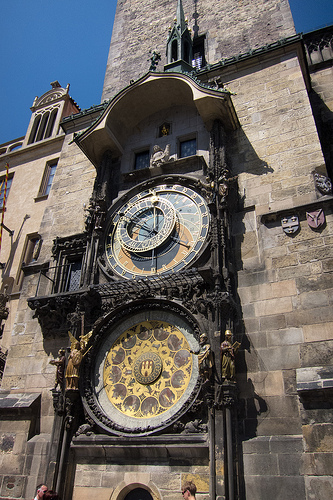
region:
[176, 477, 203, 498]
head of a person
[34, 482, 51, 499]
head of a person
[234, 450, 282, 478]
brick in a wall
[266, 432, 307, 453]
brick in a wall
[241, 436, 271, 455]
brick in a wall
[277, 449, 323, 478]
brick in a wall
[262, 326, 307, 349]
brick in a wall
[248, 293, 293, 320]
brick in a wall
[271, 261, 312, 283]
brick in a wall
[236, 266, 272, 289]
brick in a wall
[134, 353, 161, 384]
Yellow centerpiece inside of dish.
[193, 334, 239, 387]
Statues of men holding something.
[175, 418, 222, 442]
Statue of someone laying down.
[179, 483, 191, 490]
Man with glasses on his head.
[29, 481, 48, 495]
Top of walking man's head.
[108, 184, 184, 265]
Fancy clock above building.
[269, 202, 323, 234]
Small face statues on the wall.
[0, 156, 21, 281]
Red and white pole hanging from building.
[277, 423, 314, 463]
Piece of bricks on a building.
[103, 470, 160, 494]
Opening of the building.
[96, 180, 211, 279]
a clock on a wall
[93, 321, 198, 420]
symbols in a circle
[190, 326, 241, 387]
statues on the left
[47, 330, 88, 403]
statues on the right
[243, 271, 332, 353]
a stone block wall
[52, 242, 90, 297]
a window on the wall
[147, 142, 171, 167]
a statue on the top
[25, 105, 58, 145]
a row of windows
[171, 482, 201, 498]
top of a mans head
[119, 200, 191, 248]
hands on a clock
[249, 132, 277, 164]
shadow on the building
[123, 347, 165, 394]
round object on building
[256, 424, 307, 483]
brick wall in the photo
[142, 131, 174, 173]
object above the clock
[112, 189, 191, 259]
hands on the object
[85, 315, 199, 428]
yellow object on wall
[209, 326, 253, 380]
statue next to object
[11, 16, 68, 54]
blue sky above building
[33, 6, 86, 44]
sky with no clouds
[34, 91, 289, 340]
a clock on a building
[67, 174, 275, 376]
a large clock on a building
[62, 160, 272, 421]
a metal clock on a building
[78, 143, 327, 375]
a large metal clock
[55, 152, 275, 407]
a large outside clock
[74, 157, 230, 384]
a large metal outside clock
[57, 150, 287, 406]
a building with a clock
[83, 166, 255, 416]
a building with a large clock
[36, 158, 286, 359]
a building with an outside clock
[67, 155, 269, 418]
a building with a metal clock